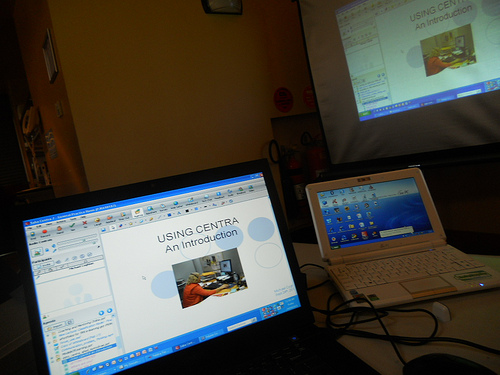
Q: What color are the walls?
A: White.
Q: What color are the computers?
A: Black and white.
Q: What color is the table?
A: White.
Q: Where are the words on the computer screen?
A: In the center.